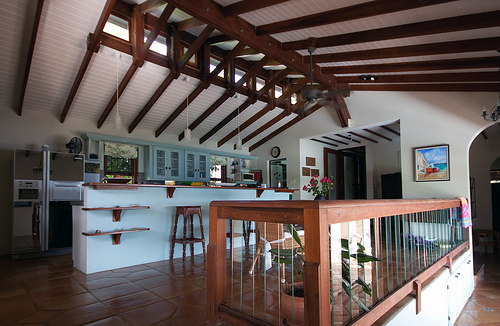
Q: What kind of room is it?
A: It is a kitchen.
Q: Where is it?
A: This is at the kitchen.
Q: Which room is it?
A: It is a kitchen.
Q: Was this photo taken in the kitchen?
A: Yes, it was taken in the kitchen.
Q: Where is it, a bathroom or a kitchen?
A: It is a kitchen.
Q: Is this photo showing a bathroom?
A: No, the picture is showing a kitchen.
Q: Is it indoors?
A: Yes, it is indoors.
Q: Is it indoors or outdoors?
A: It is indoors.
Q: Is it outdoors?
A: No, it is indoors.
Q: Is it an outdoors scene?
A: No, it is indoors.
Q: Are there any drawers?
A: No, there are no drawers.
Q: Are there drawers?
A: No, there are no drawers.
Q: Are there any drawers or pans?
A: No, there are no drawers or pans.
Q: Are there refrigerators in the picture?
A: Yes, there is a refrigerator.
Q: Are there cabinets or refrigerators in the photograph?
A: Yes, there is a refrigerator.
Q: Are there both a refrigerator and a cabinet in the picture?
A: Yes, there are both a refrigerator and a cabinet.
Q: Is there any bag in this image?
A: No, there are no bags.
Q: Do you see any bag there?
A: No, there are no bags.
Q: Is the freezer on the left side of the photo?
A: Yes, the freezer is on the left of the image.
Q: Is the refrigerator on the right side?
A: No, the refrigerator is on the left of the image.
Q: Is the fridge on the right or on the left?
A: The fridge is on the left of the image.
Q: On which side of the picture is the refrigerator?
A: The refrigerator is on the left of the image.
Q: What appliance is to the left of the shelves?
A: The appliance is a refrigerator.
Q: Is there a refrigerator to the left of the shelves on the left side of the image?
A: Yes, there is a refrigerator to the left of the shelves.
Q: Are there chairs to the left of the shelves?
A: No, there is a refrigerator to the left of the shelves.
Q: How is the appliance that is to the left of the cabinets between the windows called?
A: The appliance is a refrigerator.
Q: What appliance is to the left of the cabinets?
A: The appliance is a refrigerator.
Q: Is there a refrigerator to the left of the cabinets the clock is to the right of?
A: Yes, there is a refrigerator to the left of the cabinets.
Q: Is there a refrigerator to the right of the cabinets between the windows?
A: No, the refrigerator is to the left of the cabinets.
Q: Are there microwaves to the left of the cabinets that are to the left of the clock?
A: No, there is a refrigerator to the left of the cabinets.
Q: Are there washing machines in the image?
A: No, there are no washing machines.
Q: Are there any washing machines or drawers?
A: No, there are no washing machines or drawers.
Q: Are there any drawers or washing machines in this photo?
A: No, there are no washing machines or drawers.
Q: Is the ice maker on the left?
A: Yes, the ice maker is on the left of the image.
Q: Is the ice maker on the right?
A: No, the ice maker is on the left of the image.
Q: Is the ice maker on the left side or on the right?
A: The ice maker is on the left of the image.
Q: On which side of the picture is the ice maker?
A: The ice maker is on the left of the image.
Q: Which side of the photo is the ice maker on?
A: The ice maker is on the left of the image.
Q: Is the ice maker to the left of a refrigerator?
A: Yes, the ice maker is to the left of a refrigerator.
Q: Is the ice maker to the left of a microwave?
A: No, the ice maker is to the left of a refrigerator.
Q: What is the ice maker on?
A: The ice maker is on the freezer.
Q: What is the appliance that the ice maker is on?
A: The appliance is a refrigerator.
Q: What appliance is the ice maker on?
A: The ice maker is on the refrigerator.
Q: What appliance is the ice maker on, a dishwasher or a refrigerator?
A: The ice maker is on a refrigerator.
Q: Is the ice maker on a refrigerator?
A: Yes, the ice maker is on a refrigerator.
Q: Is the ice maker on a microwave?
A: No, the ice maker is on a refrigerator.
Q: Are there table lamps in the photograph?
A: No, there are no table lamps.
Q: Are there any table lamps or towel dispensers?
A: No, there are no table lamps or towel dispensers.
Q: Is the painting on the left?
A: No, the painting is on the right of the image.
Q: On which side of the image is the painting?
A: The painting is on the right of the image.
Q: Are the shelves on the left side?
A: Yes, the shelves are on the left of the image.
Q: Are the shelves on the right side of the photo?
A: No, the shelves are on the left of the image.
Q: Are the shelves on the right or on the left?
A: The shelves are on the left of the image.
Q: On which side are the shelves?
A: The shelves are on the left of the image.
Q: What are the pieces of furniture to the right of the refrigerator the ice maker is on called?
A: The pieces of furniture are shelves.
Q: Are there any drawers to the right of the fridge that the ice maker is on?
A: No, there are shelves to the right of the freezer.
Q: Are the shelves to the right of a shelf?
A: No, the shelves are to the right of the fridge.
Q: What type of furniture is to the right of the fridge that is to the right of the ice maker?
A: The pieces of furniture are shelves.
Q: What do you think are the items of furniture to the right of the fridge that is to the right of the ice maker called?
A: The pieces of furniture are shelves.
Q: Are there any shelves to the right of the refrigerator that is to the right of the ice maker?
A: Yes, there are shelves to the right of the fridge.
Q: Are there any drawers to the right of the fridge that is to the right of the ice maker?
A: No, there are shelves to the right of the refrigerator.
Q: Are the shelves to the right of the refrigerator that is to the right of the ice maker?
A: Yes, the shelves are to the right of the refrigerator.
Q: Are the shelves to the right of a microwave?
A: No, the shelves are to the right of the refrigerator.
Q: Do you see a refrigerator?
A: Yes, there is a refrigerator.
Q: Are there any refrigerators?
A: Yes, there is a refrigerator.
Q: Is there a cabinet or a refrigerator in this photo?
A: Yes, there is a refrigerator.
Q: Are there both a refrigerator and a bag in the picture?
A: No, there is a refrigerator but no bags.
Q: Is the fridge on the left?
A: Yes, the fridge is on the left of the image.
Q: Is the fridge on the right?
A: No, the fridge is on the left of the image.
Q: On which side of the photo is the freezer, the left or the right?
A: The freezer is on the left of the image.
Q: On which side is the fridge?
A: The fridge is on the left of the image.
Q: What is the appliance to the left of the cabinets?
A: The appliance is a refrigerator.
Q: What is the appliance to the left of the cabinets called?
A: The appliance is a refrigerator.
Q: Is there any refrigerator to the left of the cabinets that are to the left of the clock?
A: Yes, there is a refrigerator to the left of the cabinets.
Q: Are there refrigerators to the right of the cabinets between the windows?
A: No, the refrigerator is to the left of the cabinets.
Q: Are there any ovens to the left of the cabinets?
A: No, there is a refrigerator to the left of the cabinets.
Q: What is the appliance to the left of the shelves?
A: The appliance is a refrigerator.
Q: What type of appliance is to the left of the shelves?
A: The appliance is a refrigerator.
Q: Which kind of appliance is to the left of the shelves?
A: The appliance is a refrigerator.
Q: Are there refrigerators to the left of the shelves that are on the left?
A: Yes, there is a refrigerator to the left of the shelves.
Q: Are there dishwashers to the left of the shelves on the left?
A: No, there is a refrigerator to the left of the shelves.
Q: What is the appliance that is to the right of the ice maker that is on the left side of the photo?
A: The appliance is a refrigerator.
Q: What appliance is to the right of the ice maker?
A: The appliance is a refrigerator.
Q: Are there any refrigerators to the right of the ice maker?
A: Yes, there is a refrigerator to the right of the ice maker.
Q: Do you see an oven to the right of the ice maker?
A: No, there is a refrigerator to the right of the ice maker.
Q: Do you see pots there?
A: Yes, there is a pot.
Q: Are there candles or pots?
A: Yes, there is a pot.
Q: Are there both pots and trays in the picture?
A: No, there is a pot but no trays.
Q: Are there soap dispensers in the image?
A: No, there are no soap dispensers.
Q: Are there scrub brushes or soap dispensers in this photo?
A: No, there are no soap dispensers or scrub brushes.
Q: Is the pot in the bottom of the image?
A: Yes, the pot is in the bottom of the image.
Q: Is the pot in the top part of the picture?
A: No, the pot is in the bottom of the image.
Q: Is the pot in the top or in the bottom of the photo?
A: The pot is in the bottom of the image.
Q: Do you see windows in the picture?
A: Yes, there are windows.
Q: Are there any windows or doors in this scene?
A: Yes, there are windows.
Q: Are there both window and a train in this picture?
A: No, there are windows but no trains.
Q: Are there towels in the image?
A: Yes, there is a towel.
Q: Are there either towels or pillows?
A: Yes, there is a towel.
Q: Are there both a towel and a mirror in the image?
A: No, there is a towel but no mirrors.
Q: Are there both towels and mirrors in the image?
A: No, there is a towel but no mirrors.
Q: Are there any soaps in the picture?
A: No, there are no soaps.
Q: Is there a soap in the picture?
A: No, there are no soaps.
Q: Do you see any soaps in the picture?
A: No, there are no soaps.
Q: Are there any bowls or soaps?
A: No, there are no soaps or bowls.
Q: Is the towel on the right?
A: Yes, the towel is on the right of the image.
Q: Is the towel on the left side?
A: No, the towel is on the right of the image.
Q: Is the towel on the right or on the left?
A: The towel is on the right of the image.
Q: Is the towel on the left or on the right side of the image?
A: The towel is on the right of the image.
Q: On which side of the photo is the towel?
A: The towel is on the right of the image.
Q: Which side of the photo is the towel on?
A: The towel is on the right of the image.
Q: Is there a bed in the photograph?
A: No, there are no beds.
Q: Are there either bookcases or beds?
A: No, there are no beds or bookcases.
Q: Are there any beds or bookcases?
A: No, there are no beds or bookcases.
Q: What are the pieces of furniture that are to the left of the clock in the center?
A: The pieces of furniture are cabinets.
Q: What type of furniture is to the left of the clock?
A: The pieces of furniture are cabinets.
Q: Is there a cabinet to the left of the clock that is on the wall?
A: Yes, there are cabinets to the left of the clock.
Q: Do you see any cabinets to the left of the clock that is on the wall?
A: Yes, there are cabinets to the left of the clock.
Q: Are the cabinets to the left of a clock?
A: Yes, the cabinets are to the left of a clock.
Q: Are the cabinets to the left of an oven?
A: No, the cabinets are to the left of a clock.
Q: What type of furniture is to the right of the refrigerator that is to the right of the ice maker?
A: The pieces of furniture are cabinets.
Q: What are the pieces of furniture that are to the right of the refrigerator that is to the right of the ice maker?
A: The pieces of furniture are cabinets.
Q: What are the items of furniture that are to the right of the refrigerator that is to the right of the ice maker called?
A: The pieces of furniture are cabinets.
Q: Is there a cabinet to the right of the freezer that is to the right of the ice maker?
A: Yes, there are cabinets to the right of the freezer.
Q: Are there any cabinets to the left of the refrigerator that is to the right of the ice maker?
A: No, the cabinets are to the right of the freezer.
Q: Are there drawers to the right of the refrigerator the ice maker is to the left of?
A: No, there are cabinets to the right of the freezer.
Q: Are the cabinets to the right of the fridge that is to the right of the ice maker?
A: Yes, the cabinets are to the right of the refrigerator.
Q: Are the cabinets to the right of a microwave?
A: No, the cabinets are to the right of the refrigerator.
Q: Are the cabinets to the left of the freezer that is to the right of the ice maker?
A: No, the cabinets are to the right of the refrigerator.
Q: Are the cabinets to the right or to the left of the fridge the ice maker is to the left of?
A: The cabinets are to the right of the freezer.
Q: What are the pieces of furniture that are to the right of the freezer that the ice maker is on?
A: The pieces of furniture are cabinets.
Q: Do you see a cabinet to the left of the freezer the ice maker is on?
A: No, the cabinets are to the right of the fridge.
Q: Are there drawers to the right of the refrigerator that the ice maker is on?
A: No, there are cabinets to the right of the refrigerator.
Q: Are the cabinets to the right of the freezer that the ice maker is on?
A: Yes, the cabinets are to the right of the freezer.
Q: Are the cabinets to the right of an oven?
A: No, the cabinets are to the right of the freezer.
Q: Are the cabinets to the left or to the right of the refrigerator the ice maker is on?
A: The cabinets are to the right of the fridge.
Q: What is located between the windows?
A: The cabinets are between the windows.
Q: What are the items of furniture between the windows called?
A: The pieces of furniture are cabinets.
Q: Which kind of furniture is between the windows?
A: The pieces of furniture are cabinets.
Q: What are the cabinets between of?
A: The cabinets are between the windows.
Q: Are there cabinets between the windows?
A: Yes, there are cabinets between the windows.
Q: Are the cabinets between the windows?
A: Yes, the cabinets are between the windows.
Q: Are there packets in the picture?
A: No, there are no packets.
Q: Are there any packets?
A: No, there are no packets.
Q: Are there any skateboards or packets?
A: No, there are no packets or skateboards.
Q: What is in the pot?
A: The plant is in the pot.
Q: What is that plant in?
A: The plant is in the pot.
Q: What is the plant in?
A: The plant is in the pot.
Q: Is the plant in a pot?
A: Yes, the plant is in a pot.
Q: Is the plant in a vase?
A: No, the plant is in a pot.